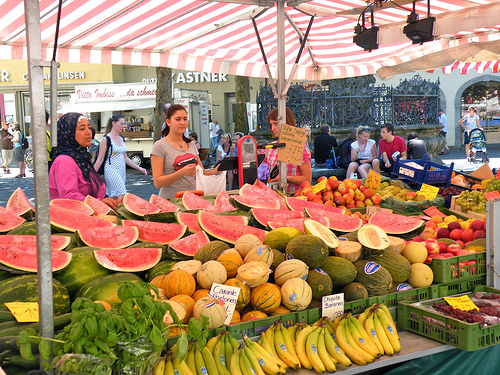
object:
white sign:
[74, 82, 174, 103]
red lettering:
[76, 86, 158, 98]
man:
[379, 123, 408, 172]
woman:
[346, 124, 377, 180]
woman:
[93, 115, 146, 198]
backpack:
[87, 134, 112, 174]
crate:
[396, 285, 499, 352]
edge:
[398, 301, 469, 352]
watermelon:
[93, 248, 162, 272]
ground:
[426, 158, 463, 192]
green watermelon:
[93, 248, 163, 272]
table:
[133, 293, 500, 374]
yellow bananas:
[302, 315, 353, 373]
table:
[154, 304, 402, 374]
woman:
[459, 105, 483, 161]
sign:
[321, 292, 344, 321]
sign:
[208, 282, 242, 326]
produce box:
[449, 179, 496, 224]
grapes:
[456, 177, 500, 216]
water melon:
[77, 226, 140, 250]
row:
[358, 303, 401, 354]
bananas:
[153, 351, 193, 375]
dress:
[104, 134, 129, 197]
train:
[391, 150, 459, 185]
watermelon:
[194, 209, 268, 244]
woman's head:
[53, 108, 98, 160]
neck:
[56, 145, 85, 158]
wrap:
[48, 112, 93, 182]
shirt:
[150, 138, 200, 199]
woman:
[149, 103, 221, 207]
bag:
[196, 164, 228, 196]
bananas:
[295, 323, 352, 373]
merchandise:
[410, 292, 500, 337]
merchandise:
[443, 294, 481, 313]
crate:
[391, 153, 454, 187]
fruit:
[399, 162, 425, 178]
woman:
[98, 109, 134, 201]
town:
[0, 0, 500, 200]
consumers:
[149, 104, 223, 202]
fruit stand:
[0, 162, 500, 375]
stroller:
[465, 128, 489, 164]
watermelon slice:
[195, 212, 265, 244]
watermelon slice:
[75, 225, 138, 248]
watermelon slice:
[49, 204, 116, 232]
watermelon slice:
[0, 235, 73, 270]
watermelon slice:
[367, 210, 424, 235]